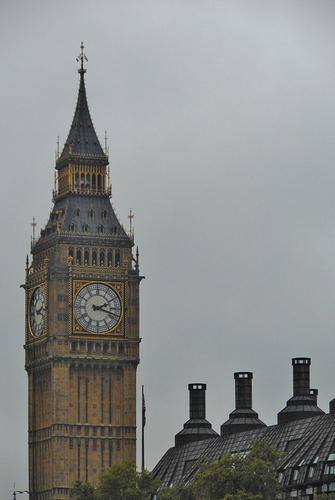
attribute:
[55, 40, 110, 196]
steeple — black, tiled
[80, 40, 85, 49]
balls — round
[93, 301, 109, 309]
hand — black, small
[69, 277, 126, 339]
clock — Round, white, black, larger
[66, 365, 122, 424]
wall — brown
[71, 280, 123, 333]
clock — White, black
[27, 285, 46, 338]
clock — White, black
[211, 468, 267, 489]
leaves — green